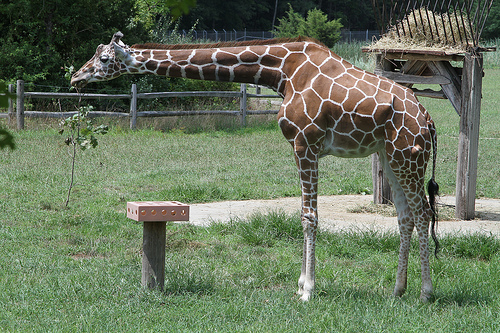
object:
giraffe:
[64, 28, 446, 305]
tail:
[426, 116, 443, 264]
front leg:
[293, 131, 322, 307]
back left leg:
[387, 135, 439, 308]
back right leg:
[380, 144, 420, 299]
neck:
[135, 38, 303, 89]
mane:
[130, 34, 313, 49]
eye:
[98, 54, 113, 65]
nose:
[68, 76, 82, 85]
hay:
[366, 7, 474, 70]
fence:
[0, 78, 283, 133]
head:
[67, 27, 139, 95]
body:
[271, 40, 437, 305]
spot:
[306, 71, 336, 101]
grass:
[1, 38, 500, 332]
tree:
[55, 64, 111, 210]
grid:
[379, 0, 475, 51]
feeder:
[356, 0, 496, 222]